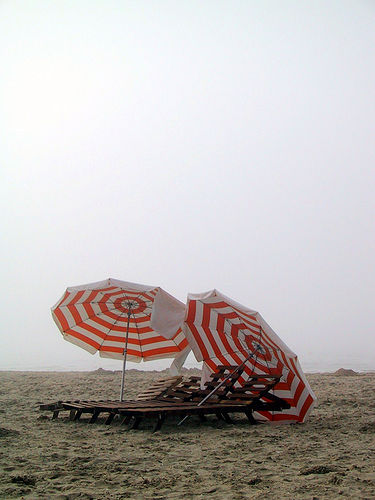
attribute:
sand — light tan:
[4, 426, 369, 492]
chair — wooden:
[39, 375, 184, 423]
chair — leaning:
[116, 372, 283, 432]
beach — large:
[1, 371, 374, 497]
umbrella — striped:
[46, 273, 193, 364]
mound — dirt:
[316, 360, 372, 402]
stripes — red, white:
[63, 323, 105, 347]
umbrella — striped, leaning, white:
[51, 277, 192, 402]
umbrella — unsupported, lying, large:
[175, 289, 313, 424]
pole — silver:
[120, 310, 129, 400]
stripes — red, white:
[54, 279, 324, 431]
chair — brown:
[117, 368, 286, 425]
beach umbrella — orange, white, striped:
[50, 278, 187, 400]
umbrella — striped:
[45, 271, 193, 396]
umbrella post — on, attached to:
[117, 303, 131, 401]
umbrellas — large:
[48, 274, 316, 426]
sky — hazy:
[5, 7, 373, 272]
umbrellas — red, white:
[44, 269, 320, 415]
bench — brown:
[119, 373, 290, 430]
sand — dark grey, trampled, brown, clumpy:
[0, 368, 374, 498]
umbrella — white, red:
[75, 299, 157, 350]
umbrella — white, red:
[197, 311, 261, 368]